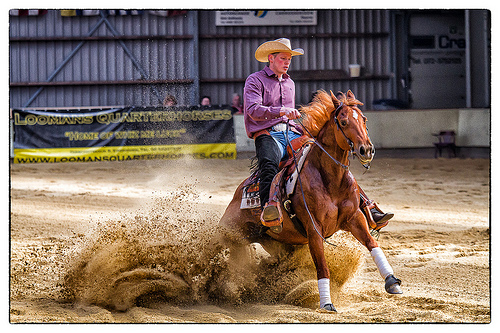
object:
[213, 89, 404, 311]
horse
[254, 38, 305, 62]
cowboy hat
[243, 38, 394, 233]
person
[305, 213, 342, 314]
legs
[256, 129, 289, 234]
legs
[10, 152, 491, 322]
sand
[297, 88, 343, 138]
hair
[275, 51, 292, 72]
face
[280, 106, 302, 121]
hand